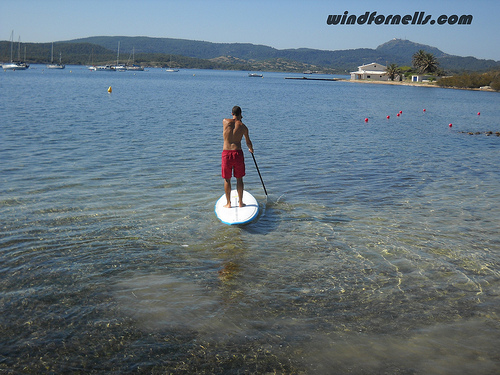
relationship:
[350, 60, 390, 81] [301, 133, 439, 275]
house by water'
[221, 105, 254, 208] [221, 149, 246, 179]
man wearing shorts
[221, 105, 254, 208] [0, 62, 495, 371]
man in water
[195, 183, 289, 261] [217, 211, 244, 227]
board with stripe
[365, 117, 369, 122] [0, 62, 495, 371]
buoy in water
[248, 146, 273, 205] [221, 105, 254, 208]
paddle in man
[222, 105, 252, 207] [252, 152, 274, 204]
man holding paddle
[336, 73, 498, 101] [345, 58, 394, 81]
sea shore live house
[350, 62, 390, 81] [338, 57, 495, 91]
house on island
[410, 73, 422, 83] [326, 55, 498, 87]
gazebo on island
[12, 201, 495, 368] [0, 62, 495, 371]
sea grass in water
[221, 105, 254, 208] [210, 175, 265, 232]
man on paddle board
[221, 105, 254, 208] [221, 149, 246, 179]
man in shorts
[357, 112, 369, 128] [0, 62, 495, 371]
buoy floating in water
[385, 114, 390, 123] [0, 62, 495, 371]
buoy floating in water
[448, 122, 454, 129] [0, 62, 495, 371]
buoy floating in water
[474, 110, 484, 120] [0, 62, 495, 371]
buoy floating in water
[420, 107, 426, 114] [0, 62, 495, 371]
buoy floating in water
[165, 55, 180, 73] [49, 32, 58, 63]
sailboat with sails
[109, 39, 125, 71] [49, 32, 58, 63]
sailboat with sails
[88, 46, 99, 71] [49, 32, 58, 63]
sailboat with sails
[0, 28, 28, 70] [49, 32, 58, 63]
sailboat with sails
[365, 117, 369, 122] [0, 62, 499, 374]
buoy in water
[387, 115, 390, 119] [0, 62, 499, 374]
buoy in water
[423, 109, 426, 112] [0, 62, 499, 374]
buoy in water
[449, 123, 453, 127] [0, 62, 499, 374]
buoy in water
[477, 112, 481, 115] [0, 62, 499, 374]
buoy in water